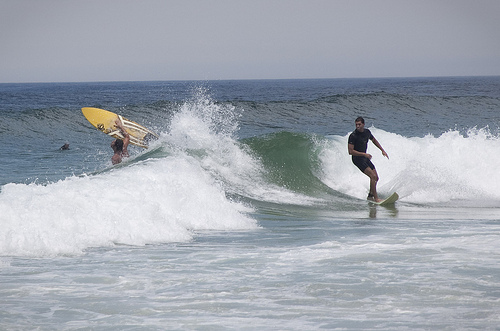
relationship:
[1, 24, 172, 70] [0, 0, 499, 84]
cloud in sky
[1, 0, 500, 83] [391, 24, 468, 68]
cloud in blue sky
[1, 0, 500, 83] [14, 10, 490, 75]
cloud in blue sky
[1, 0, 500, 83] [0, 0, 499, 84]
cloud in sky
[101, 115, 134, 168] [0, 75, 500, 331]
man in ocean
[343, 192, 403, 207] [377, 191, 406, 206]
surfboard has tip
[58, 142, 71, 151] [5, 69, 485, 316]
swimmer in water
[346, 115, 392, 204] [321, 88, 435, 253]
man on surfboard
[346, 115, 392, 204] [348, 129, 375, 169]
man wearing wet suit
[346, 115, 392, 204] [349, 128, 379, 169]
man wearing wet suit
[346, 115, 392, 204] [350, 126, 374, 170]
man wearing wetsuit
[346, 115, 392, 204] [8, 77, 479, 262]
man riding wave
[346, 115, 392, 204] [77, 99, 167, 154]
man holding surfboard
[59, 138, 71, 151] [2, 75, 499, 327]
swimmer in ocean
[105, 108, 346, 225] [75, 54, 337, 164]
wave in ocean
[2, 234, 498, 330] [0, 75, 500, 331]
foam on top of ocean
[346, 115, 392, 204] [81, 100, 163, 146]
man falling off surfboard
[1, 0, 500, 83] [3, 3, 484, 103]
cloud in sky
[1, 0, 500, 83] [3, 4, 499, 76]
cloud in sky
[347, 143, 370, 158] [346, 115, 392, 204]
arm on man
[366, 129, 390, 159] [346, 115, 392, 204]
arm on man